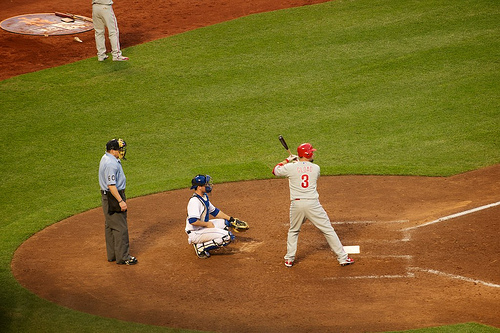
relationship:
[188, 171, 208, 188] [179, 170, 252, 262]
helmet on catcher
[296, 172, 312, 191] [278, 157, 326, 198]
number on jersey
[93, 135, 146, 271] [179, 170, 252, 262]
umpire behind catcher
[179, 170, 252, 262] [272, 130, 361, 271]
catcher behind batter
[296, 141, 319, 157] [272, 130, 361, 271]
helmet on batter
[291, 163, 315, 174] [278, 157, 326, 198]
writing on jersey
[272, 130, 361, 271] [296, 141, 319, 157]
batter wearing helmet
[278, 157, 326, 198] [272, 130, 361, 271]
jersey on batter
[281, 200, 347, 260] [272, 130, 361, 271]
pants on batter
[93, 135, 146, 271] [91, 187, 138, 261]
umpire wearing slacks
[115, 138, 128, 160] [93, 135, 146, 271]
shield on umpire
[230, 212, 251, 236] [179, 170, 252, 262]
glove on catcher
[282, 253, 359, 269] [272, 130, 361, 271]
shoes on batter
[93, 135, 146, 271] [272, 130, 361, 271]
umpire watching batter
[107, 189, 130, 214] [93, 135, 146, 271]
apron on umpire